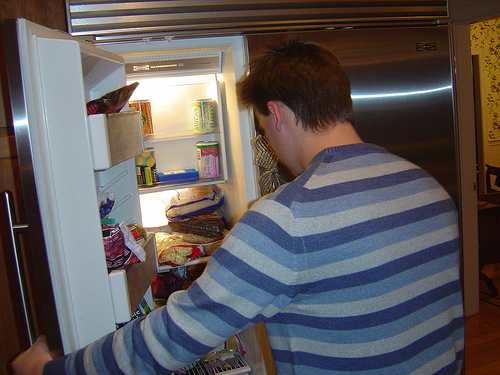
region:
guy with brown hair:
[145, 41, 452, 261]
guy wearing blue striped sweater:
[191, 30, 498, 372]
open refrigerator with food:
[10, 17, 207, 299]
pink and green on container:
[186, 130, 232, 204]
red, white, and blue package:
[83, 207, 168, 279]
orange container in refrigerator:
[128, 96, 173, 141]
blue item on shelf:
[156, 161, 218, 186]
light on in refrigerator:
[97, 45, 225, 104]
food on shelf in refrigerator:
[132, 187, 239, 287]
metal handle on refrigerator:
[2, 161, 100, 373]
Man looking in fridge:
[118, 51, 468, 373]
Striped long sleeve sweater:
[165, 135, 482, 372]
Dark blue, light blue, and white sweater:
[213, 146, 480, 371]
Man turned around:
[212, 68, 453, 370]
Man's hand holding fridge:
[2, 290, 78, 373]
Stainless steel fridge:
[107, 0, 490, 342]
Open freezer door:
[16, 15, 290, 372]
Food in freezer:
[87, 73, 239, 350]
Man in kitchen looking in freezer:
[13, 3, 478, 366]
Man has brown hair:
[232, 31, 367, 144]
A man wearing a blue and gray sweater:
[6, 28, 471, 366]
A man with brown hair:
[228, 30, 480, 373]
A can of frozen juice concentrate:
[188, 138, 230, 185]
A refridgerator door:
[0, 13, 168, 365]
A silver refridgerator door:
[343, 45, 473, 196]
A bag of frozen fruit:
[97, 218, 170, 273]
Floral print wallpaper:
[466, 13, 499, 150]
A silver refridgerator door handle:
[3, 184, 43, 373]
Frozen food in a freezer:
[158, 190, 226, 271]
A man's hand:
[11, 316, 65, 373]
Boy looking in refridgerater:
[175, 52, 487, 372]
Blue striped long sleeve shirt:
[271, 155, 430, 372]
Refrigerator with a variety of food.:
[5, 50, 252, 374]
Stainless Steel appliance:
[323, 18, 472, 188]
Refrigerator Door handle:
[1, 187, 47, 371]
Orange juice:
[132, 145, 164, 188]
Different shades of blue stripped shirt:
[246, 163, 471, 368]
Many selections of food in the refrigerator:
[18, 10, 253, 372]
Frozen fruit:
[97, 223, 144, 270]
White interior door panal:
[8, 11, 148, 333]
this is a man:
[243, 24, 451, 369]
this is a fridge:
[378, 27, 438, 104]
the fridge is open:
[90, 23, 227, 175]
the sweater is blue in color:
[300, 180, 425, 366]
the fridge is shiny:
[375, 71, 435, 133]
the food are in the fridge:
[152, 180, 234, 245]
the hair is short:
[262, 49, 319, 85]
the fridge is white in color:
[50, 159, 84, 213]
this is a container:
[198, 139, 220, 179]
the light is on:
[158, 75, 189, 122]